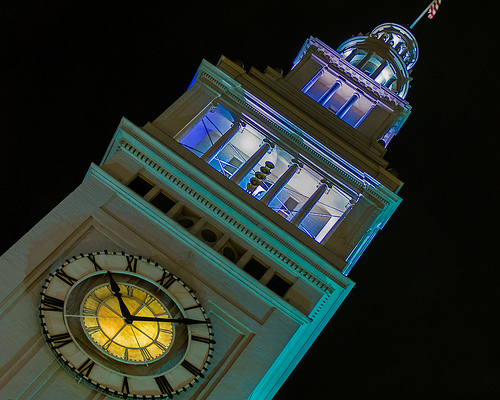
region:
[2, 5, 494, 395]
night view of a white steeple at an angle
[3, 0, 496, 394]
black sky behind a white steeple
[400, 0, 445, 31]
American flag at the top of a steeple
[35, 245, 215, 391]
white clock face with black roman numberals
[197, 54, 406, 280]
blue trim around portion of a steeple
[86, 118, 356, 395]
blue trim on a steeple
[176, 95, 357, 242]
five lit windows in a steeple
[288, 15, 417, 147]
trim lighting on a tall steeple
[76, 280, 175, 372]
yellow faced clock face inside a larger one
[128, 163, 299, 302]
black windows in a steeple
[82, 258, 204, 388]
yellow face on clock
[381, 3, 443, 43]
US flag on tower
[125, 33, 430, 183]
tower is lit blue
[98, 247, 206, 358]
black hands on clock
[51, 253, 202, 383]
roman numerals on clock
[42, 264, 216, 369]
roman numerals are black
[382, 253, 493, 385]
sky is black and dark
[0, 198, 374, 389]
clock tower is white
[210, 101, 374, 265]
white columns above clock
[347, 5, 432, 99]
top of tower is round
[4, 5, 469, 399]
clock tower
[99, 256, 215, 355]
two black clock hands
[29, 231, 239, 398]
roman numerals around the circumference of the clock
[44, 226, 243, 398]
clock indicating it's a little past 10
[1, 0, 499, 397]
sky is pitch black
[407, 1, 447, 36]
flag on top of the tower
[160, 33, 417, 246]
blue and purple lighting on the top of the tower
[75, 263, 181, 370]
center of the clock is yellow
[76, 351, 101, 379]
upside down roman numeral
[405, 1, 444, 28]
flag on a pole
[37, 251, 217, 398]
The clock on the white tower is currently at 10:07.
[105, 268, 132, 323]
The tower clock's hour hand.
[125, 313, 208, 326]
The tower clock's minute hand.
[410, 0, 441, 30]
The flag on top of the white tower stands slack.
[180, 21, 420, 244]
Lights inside the white tower give a beautiful ambience.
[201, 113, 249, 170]
A column in the white tower gives interesting architectural detail.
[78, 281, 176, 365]
A yellow light illuminates the tower clock face.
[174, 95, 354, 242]
Cross braces within the white tower provide stability.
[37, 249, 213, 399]
The clock face is marked with Roman numerals.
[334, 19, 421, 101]
The top of the tower is cylindrical, contrasting with the squareness of the rest of the tower.